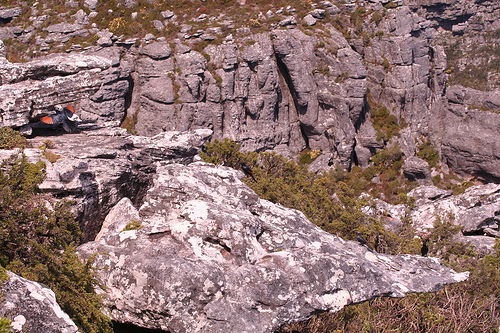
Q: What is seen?
A: Rocks.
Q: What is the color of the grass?
A: Green.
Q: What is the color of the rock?
A: Grey.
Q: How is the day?
A: Sunny.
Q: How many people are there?
A: No one.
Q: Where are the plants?
A: In between the rock.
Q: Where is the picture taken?
A: Mountain.